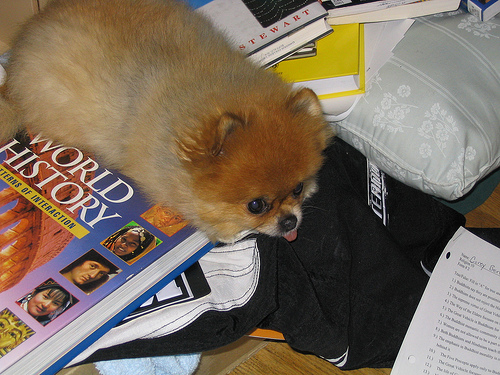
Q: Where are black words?
A: On white paper.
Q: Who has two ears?
A: The dog.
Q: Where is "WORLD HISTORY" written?
A: On a book.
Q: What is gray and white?
A: A pillow.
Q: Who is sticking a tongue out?
A: Dog.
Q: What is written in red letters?
A: "STEWART".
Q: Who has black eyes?
A: The dog.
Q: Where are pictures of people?
A: On World History book.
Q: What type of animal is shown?
A: Dog.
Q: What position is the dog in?
A: Laying down.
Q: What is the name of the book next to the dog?
A: World History.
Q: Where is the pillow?
A: Under the books.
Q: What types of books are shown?
A: Hardback books.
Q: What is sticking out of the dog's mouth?
A: Tongue.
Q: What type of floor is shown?
A: Hardwood.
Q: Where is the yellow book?
A: On the pillow.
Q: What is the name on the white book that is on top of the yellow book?
A: STEWART.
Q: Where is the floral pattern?
A: On the pillow.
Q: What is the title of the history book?
A: "World History".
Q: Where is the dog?
A: On a pile of clothes.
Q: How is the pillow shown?
A: Without a pillow case.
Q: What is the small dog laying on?
A: Textbooks.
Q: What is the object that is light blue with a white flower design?
A: A pillow.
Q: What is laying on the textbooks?
A: A small dog.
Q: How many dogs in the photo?
A: One.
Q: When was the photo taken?
A: Day time.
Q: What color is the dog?
A: Brown.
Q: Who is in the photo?
A: A dog.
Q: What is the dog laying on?
A: A table.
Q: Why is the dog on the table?
A: Resting.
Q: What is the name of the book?
A: World history.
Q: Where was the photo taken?
A: In a bedroom.